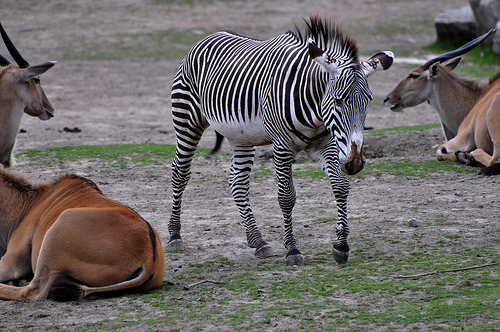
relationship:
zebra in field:
[158, 15, 396, 270] [3, 1, 498, 329]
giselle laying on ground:
[385, 28, 499, 174] [3, 1, 498, 329]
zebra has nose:
[158, 15, 396, 270] [349, 141, 360, 173]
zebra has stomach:
[158, 15, 396, 270] [204, 111, 270, 147]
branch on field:
[396, 260, 500, 282] [3, 1, 498, 329]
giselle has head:
[385, 28, 499, 174] [383, 64, 438, 116]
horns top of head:
[420, 27, 498, 67] [383, 64, 438, 116]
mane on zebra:
[292, 14, 361, 63] [158, 15, 396, 270]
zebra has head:
[158, 15, 396, 270] [305, 36, 395, 176]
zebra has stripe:
[158, 15, 396, 270] [234, 153, 256, 158]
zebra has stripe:
[158, 15, 396, 270] [233, 157, 254, 162]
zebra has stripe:
[158, 15, 396, 270] [172, 118, 201, 137]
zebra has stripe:
[158, 15, 396, 270] [177, 134, 198, 148]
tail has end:
[50, 273, 149, 304] [49, 279, 84, 305]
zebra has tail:
[158, 15, 396, 270] [208, 130, 227, 156]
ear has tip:
[307, 36, 343, 74] [307, 38, 316, 44]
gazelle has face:
[385, 28, 499, 174] [383, 64, 438, 116]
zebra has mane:
[158, 15, 396, 270] [292, 14, 361, 63]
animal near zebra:
[1, 160, 167, 302] [158, 15, 396, 270]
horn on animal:
[2, 25, 33, 68] [0, 23, 58, 163]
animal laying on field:
[1, 160, 167, 302] [3, 1, 498, 329]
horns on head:
[420, 27, 498, 67] [383, 64, 438, 116]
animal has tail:
[1, 160, 167, 302] [50, 273, 149, 304]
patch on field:
[55, 61, 169, 143] [3, 1, 498, 329]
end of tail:
[49, 279, 84, 305] [50, 273, 149, 304]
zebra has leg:
[158, 15, 396, 270] [271, 142, 306, 266]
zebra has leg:
[158, 15, 396, 270] [309, 138, 354, 267]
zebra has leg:
[158, 15, 396, 270] [168, 74, 209, 247]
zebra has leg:
[158, 15, 396, 270] [225, 138, 276, 261]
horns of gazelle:
[420, 27, 498, 67] [385, 28, 499, 174]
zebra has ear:
[158, 15, 396, 270] [307, 36, 343, 74]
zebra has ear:
[158, 15, 396, 270] [360, 47, 396, 76]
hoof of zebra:
[331, 246, 350, 265] [158, 15, 396, 270]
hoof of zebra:
[284, 256, 306, 269] [158, 15, 396, 270]